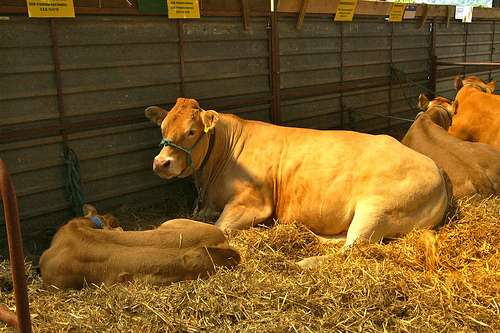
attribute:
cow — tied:
[400, 94, 498, 199]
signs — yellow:
[24, 1, 409, 25]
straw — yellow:
[175, 231, 190, 248]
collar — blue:
[80, 210, 106, 229]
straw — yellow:
[3, 182, 498, 330]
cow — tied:
[395, 64, 498, 202]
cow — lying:
[136, 89, 462, 260]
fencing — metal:
[231, 36, 363, 109]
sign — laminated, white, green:
[25, 0, 79, 20]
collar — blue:
[82, 208, 111, 226]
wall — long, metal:
[5, 50, 495, 241]